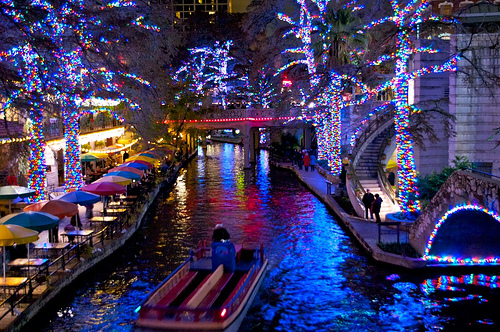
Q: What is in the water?
A: Boat.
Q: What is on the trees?
A: Lights.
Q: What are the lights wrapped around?
A: Trees.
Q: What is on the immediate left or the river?
A: Row of tables.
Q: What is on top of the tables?
A: Umbrellas.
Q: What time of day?
A: It is night.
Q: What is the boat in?
A: The canal.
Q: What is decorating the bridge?
A: Lights.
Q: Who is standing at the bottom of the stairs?
A: Two people.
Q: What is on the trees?
A: Colorful lights.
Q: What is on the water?
A: Boat.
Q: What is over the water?
A: Bridge.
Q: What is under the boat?
A: Water.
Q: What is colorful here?
A: Umbrellas.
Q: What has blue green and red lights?
A: The tree.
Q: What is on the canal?
A: Empty boat.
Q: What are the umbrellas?
A: Yellow blue red and green.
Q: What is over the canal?
A: The lit bridge.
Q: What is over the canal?
A: The bridge with red light.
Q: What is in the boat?
A: Captain.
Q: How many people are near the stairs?
A: Two.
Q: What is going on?
A: A celebration.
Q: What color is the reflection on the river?
A: Blue.